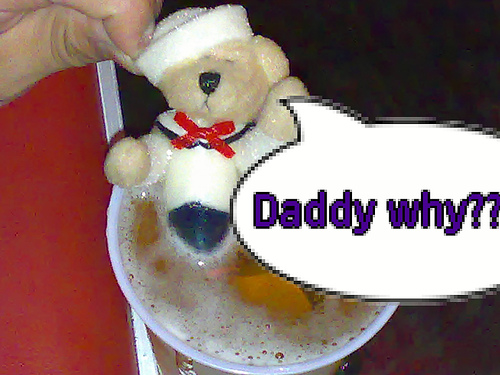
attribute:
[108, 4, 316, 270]
bear — white, toy, tiny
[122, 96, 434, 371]
cup — clear, plastic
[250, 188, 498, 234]
quotation — white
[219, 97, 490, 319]
outline — black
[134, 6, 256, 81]
cap — whtie, tiny, white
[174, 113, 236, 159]
ribbon — red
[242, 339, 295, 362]
bubble — white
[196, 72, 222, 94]
nose — black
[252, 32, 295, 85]
ear — brown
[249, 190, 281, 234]
letter — blue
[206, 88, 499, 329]
bubble — white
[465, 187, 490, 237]
question mark — blue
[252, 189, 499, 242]
text — blue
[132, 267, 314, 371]
bubbles — white, foamy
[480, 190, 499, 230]
question mark — blue